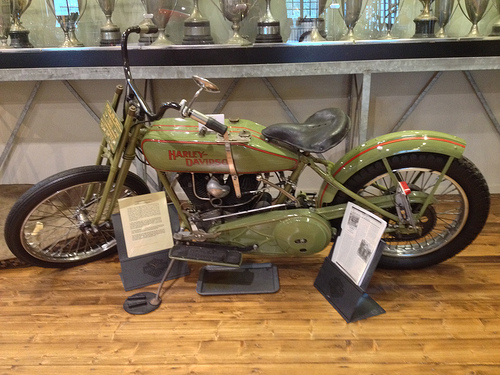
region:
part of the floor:
[444, 291, 478, 337]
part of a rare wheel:
[442, 176, 482, 233]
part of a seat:
[293, 122, 323, 148]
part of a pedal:
[179, 232, 231, 277]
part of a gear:
[191, 108, 231, 137]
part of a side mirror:
[194, 67, 229, 117]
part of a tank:
[167, 125, 206, 167]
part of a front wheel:
[31, 182, 87, 244]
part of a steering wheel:
[93, 8, 174, 127]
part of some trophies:
[231, 2, 363, 32]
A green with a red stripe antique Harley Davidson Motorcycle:
[0, 25, 498, 257]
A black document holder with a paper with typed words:
[108, 185, 189, 291]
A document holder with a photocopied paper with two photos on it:
[315, 195, 385, 331]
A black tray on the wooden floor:
[196, 261, 290, 312]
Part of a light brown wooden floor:
[1, 322, 497, 373]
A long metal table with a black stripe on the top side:
[1, 34, 498, 184]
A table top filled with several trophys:
[0, 0, 499, 49]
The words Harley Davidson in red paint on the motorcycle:
[166, 144, 242, 175]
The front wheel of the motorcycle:
[3, 165, 147, 272]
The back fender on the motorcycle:
[313, 133, 475, 206]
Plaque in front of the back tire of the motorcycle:
[308, 198, 398, 327]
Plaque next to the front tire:
[105, 195, 183, 296]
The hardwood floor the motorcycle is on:
[2, 187, 498, 372]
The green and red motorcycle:
[2, 23, 492, 284]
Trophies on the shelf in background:
[14, 0, 495, 52]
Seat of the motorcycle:
[254, 102, 353, 167]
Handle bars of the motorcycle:
[116, 23, 235, 136]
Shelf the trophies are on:
[0, 38, 498, 85]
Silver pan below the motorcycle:
[194, 257, 286, 307]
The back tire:
[337, 151, 493, 273]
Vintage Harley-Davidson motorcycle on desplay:
[3, 15, 492, 329]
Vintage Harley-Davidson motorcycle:
[4, 22, 491, 336]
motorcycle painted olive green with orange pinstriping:
[13, 30, 494, 332]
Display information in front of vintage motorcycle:
[103, 187, 399, 330]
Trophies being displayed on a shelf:
[2, 1, 497, 54]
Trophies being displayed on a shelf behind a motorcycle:
[0, 0, 497, 297]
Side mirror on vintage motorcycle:
[158, 66, 237, 134]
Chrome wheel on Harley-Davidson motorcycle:
[6, 145, 149, 275]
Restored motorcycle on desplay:
[10, 21, 495, 329]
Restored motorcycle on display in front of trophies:
[1, 0, 492, 329]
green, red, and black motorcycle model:
[0, 17, 495, 322]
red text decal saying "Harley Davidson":
[161, 142, 235, 175]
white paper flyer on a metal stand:
[314, 196, 405, 333]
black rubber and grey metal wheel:
[4, 146, 167, 286]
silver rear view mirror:
[173, 66, 223, 123]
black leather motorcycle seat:
[256, 97, 356, 159]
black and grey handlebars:
[112, 14, 252, 143]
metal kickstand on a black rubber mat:
[117, 256, 182, 323]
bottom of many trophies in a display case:
[0, 8, 498, 48]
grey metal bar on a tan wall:
[0, 82, 61, 167]